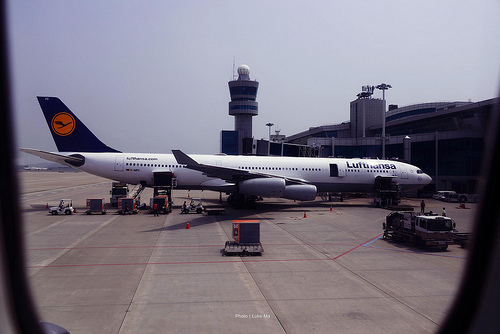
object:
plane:
[14, 96, 432, 209]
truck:
[48, 198, 77, 215]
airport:
[0, 65, 495, 333]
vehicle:
[383, 209, 455, 252]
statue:
[228, 65, 259, 154]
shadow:
[143, 194, 305, 229]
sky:
[0, 0, 500, 165]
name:
[344, 161, 396, 169]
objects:
[86, 198, 104, 214]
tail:
[36, 96, 121, 153]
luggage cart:
[115, 198, 139, 216]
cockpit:
[413, 168, 432, 182]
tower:
[226, 64, 259, 154]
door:
[328, 164, 343, 177]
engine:
[237, 175, 284, 197]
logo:
[51, 111, 77, 137]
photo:
[0, 0, 499, 333]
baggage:
[157, 189, 167, 195]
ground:
[0, 171, 480, 333]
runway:
[18, 171, 476, 333]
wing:
[170, 149, 308, 185]